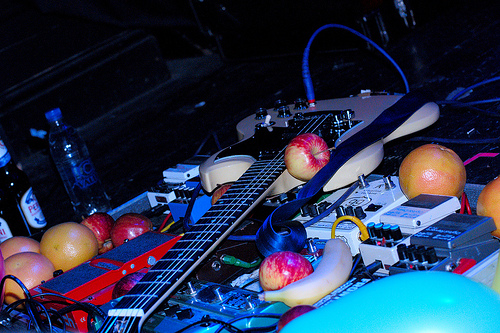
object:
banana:
[257, 237, 353, 309]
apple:
[255, 250, 315, 293]